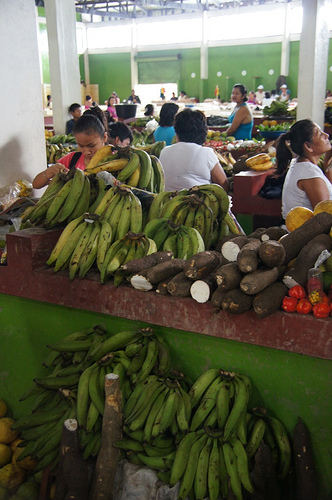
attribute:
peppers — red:
[279, 285, 324, 317]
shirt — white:
[280, 159, 329, 226]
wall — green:
[48, 43, 331, 103]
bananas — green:
[50, 214, 110, 278]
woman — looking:
[33, 106, 125, 204]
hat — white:
[258, 86, 264, 91]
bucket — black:
[113, 103, 136, 120]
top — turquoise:
[228, 102, 253, 138]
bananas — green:
[28, 171, 100, 227]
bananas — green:
[157, 181, 228, 248]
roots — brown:
[223, 232, 248, 261]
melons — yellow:
[1, 399, 39, 494]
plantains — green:
[176, 418, 246, 493]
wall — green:
[4, 214, 331, 498]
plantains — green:
[190, 371, 261, 431]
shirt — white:
[159, 141, 220, 190]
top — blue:
[153, 122, 179, 145]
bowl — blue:
[183, 101, 194, 109]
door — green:
[138, 55, 181, 85]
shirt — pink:
[59, 152, 104, 179]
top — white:
[277, 159, 332, 229]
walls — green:
[43, 34, 327, 114]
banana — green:
[145, 185, 225, 245]